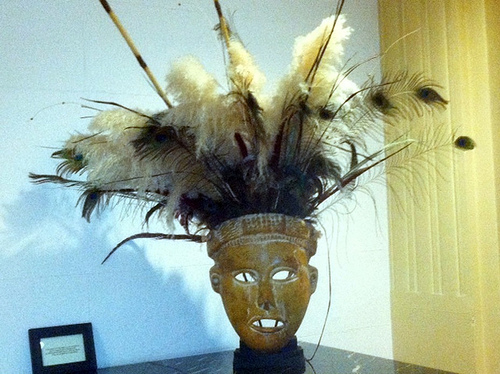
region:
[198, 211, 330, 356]
a sculpture of a face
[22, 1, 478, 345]
a sculpture with peacock feathers on top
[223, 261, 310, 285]
the eyes of a sculpture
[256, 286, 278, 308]
the nose of a sculpture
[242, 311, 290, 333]
the mouth of a sculpture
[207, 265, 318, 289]
the eyes and ears of a sculpture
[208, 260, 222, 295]
the right ear of a sculpture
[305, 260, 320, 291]
the left ear of a sculpture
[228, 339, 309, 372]
the stand of a sculpture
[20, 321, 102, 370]
a sign beside a sculpture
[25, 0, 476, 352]
a brown mask with a feathered headdress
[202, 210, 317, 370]
the mask on a black stand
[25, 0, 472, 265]
the things coming out of the mask headdress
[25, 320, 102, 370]
small black framed sign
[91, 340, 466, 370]
the table the mask is on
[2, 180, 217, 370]
shadow on the wall from the mask headdress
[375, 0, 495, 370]
yellow part of a wall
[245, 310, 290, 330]
the mouth on the mask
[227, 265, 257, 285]
left eye on the mask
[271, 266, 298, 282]
the right eye on the mask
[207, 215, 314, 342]
A face on the mask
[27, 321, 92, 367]
A picture frame against the wall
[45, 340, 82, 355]
Words in the picture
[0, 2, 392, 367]
A white wall behind the plant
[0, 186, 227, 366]
A shadow on the wall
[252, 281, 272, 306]
A nose on the mask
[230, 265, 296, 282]
Eyes of the mask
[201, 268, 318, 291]
Ears on the mask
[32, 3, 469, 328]
A plant behind the mask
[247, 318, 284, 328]
A mouth on the mask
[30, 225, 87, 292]
The wall in the background is white.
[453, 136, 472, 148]
The door knob is dark in color.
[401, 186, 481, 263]
The door on the side is white.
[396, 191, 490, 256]
The door is made of wood.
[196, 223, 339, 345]
The statue is brown.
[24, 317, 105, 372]
The picture frame is black.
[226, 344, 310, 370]
The statue stand is black.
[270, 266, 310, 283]
The eye is white.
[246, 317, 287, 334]
The mouth is white.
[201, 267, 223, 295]
The ear is brown.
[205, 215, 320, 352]
A weird looking mask.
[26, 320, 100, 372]
Some text in a black frame.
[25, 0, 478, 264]
A big bouquet of black and white feathers.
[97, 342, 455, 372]
A black marble counter top.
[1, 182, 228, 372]
A shadow on the wall.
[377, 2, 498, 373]
A large tan object.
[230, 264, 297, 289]
Two eye holds in the face of a mask.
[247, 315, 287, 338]
A mouth hole in the face of a mask.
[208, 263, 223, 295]
An ear on a weird mask.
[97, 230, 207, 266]
A black feather.